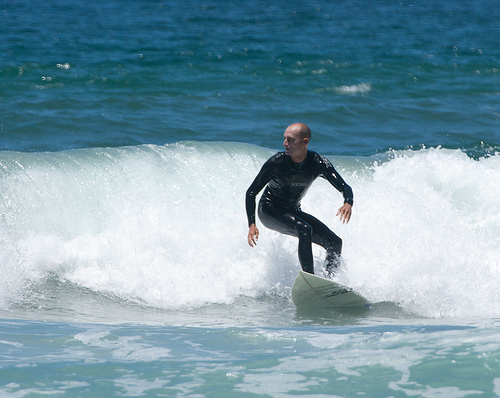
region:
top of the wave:
[448, 152, 485, 177]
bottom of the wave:
[137, 245, 162, 265]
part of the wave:
[428, 207, 435, 228]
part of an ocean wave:
[147, 225, 171, 258]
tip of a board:
[298, 260, 310, 285]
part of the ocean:
[170, 328, 184, 330]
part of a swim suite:
[280, 205, 286, 226]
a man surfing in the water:
[206, 95, 377, 299]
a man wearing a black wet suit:
[228, 109, 385, 325]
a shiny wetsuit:
[245, 149, 392, 281]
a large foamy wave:
[37, 93, 456, 334]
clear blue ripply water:
[18, 35, 458, 155]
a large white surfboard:
[263, 248, 392, 356]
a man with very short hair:
[245, 100, 369, 219]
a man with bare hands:
[220, 160, 382, 268]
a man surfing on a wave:
[48, 75, 433, 366]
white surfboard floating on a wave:
[269, 267, 405, 342]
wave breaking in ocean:
[3, 149, 498, 303]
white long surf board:
[289, 268, 371, 313]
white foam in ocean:
[23, 218, 260, 317]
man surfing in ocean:
[247, 124, 383, 332]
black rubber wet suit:
[249, 152, 350, 272]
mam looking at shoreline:
[244, 120, 386, 320]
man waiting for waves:
[242, 117, 376, 327]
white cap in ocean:
[319, 73, 376, 94]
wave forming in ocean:
[10, 52, 493, 87]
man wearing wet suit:
[244, 111, 356, 276]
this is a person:
[236, 104, 403, 321]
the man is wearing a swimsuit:
[225, 94, 355, 284]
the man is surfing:
[225, 108, 372, 332]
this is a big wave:
[1, 145, 498, 315]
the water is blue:
[2, 1, 499, 141]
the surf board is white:
[273, 263, 385, 320]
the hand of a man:
[236, 155, 282, 249]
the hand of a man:
[320, 163, 360, 230]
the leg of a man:
[283, 215, 314, 280]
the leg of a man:
[307, 210, 349, 290]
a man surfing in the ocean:
[206, 106, 411, 346]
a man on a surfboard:
[203, 102, 404, 344]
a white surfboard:
[239, 248, 407, 342]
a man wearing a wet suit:
[233, 110, 385, 356]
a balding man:
[254, 101, 339, 176]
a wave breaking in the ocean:
[19, 69, 496, 355]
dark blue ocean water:
[3, 7, 490, 387]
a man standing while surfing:
[237, 112, 408, 339]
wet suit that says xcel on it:
[284, 177, 310, 193]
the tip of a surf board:
[278, 241, 391, 347]